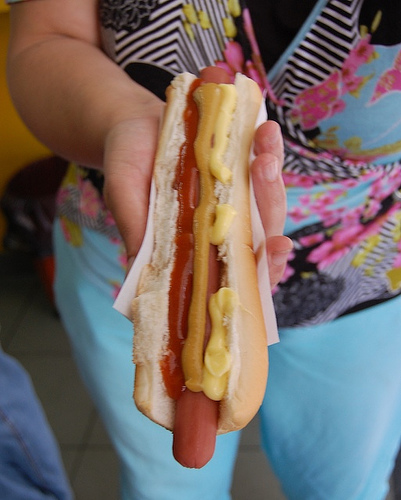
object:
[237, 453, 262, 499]
ground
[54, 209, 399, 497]
pants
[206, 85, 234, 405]
cheese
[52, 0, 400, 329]
top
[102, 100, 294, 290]
hand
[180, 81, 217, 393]
mustard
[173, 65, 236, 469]
dog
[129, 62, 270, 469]
bun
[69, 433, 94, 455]
grout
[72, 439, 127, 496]
tile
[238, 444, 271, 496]
tile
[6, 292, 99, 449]
tile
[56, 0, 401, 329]
shirt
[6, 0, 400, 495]
person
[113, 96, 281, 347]
napkin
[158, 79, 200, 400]
ketchup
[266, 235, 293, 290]
finger